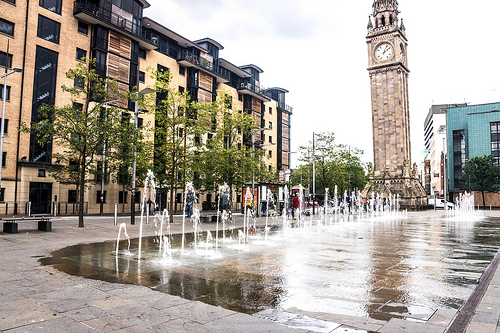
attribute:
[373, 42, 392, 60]
clock — black, white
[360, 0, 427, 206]
tower — tan, clock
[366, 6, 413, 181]
clock tower — tan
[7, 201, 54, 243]
bench — small, cement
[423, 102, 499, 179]
building — tall, blue, apartment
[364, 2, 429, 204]
clock tower — large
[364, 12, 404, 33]
spires — ornated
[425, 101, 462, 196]
building — white and grey, tall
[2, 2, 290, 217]
building — tan, brown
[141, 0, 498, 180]
clouds — dark grey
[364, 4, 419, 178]
clock tower — tall, brown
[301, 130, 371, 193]
trees — green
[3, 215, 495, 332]
ground — wet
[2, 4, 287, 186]
building — large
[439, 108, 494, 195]
building — aqua-colored, distant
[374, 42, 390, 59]
clock — round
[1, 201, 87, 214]
fence — black, wrought, iron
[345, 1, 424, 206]
tower — tan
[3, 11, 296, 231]
building — large, tan and black